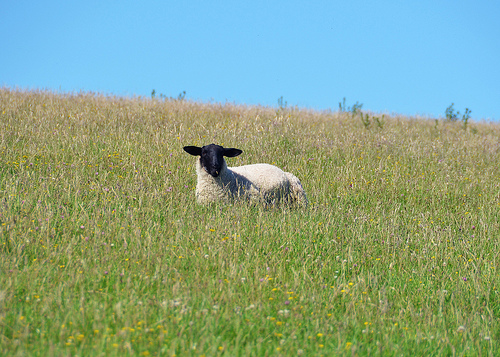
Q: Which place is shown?
A: It is a field.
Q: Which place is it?
A: It is a field.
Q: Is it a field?
A: Yes, it is a field.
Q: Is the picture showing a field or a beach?
A: It is showing a field.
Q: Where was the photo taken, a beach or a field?
A: It was taken at a field.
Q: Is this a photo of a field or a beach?
A: It is showing a field.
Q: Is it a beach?
A: No, it is a field.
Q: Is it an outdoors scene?
A: Yes, it is outdoors.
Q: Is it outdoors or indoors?
A: It is outdoors.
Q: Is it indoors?
A: No, it is outdoors.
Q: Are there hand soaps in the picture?
A: No, there are no hand soaps.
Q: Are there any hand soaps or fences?
A: No, there are no hand soaps or fences.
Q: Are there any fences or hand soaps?
A: No, there are no hand soaps or fences.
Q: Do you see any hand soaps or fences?
A: No, there are no hand soaps or fences.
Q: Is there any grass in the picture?
A: Yes, there is grass.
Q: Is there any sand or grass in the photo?
A: Yes, there is grass.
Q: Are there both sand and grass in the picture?
A: No, there is grass but no sand.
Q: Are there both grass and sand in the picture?
A: No, there is grass but no sand.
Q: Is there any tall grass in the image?
A: Yes, there is tall grass.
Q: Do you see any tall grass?
A: Yes, there is tall grass.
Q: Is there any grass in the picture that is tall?
A: Yes, there is grass that is tall.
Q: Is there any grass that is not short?
A: Yes, there is tall grass.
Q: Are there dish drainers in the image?
A: No, there are no dish drainers.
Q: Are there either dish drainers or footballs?
A: No, there are no dish drainers or footballs.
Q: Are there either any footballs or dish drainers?
A: No, there are no dish drainers or footballs.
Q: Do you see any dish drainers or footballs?
A: No, there are no dish drainers or footballs.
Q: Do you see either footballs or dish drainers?
A: No, there are no dish drainers or footballs.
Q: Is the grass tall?
A: Yes, the grass is tall.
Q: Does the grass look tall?
A: Yes, the grass is tall.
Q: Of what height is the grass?
A: The grass is tall.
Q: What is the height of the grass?
A: The grass is tall.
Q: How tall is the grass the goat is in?
A: The grass is tall.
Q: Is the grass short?
A: No, the grass is tall.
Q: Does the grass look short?
A: No, the grass is tall.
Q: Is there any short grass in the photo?
A: No, there is grass but it is tall.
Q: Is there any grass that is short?
A: No, there is grass but it is tall.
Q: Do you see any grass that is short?
A: No, there is grass but it is tall.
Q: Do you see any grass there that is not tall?
A: No, there is grass but it is tall.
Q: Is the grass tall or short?
A: The grass is tall.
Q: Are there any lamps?
A: No, there are no lamps.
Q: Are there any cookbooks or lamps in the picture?
A: No, there are no lamps or cookbooks.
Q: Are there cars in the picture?
A: No, there are no cars.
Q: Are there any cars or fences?
A: No, there are no cars or fences.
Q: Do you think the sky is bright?
A: Yes, the sky is bright.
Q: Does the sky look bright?
A: Yes, the sky is bright.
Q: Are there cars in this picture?
A: No, there are no cars.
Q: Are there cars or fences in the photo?
A: No, there are no cars or fences.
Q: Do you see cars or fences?
A: No, there are no cars or fences.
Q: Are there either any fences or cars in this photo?
A: No, there are no cars or fences.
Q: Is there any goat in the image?
A: Yes, there is a goat.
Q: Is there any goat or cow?
A: Yes, there is a goat.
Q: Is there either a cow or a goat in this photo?
A: Yes, there is a goat.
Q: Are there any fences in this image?
A: No, there are no fences.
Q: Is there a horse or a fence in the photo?
A: No, there are no fences or horses.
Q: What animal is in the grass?
A: The animal is a goat.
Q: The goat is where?
A: The goat is in the grass.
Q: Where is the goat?
A: The goat is in the grass.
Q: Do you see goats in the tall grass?
A: Yes, there is a goat in the grass.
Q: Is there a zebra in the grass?
A: No, there is a goat in the grass.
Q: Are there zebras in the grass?
A: No, there is a goat in the grass.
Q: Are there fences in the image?
A: No, there are no fences.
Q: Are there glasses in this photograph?
A: No, there are no glasses.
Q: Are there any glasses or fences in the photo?
A: No, there are no glasses or fences.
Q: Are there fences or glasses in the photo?
A: No, there are no glasses or fences.